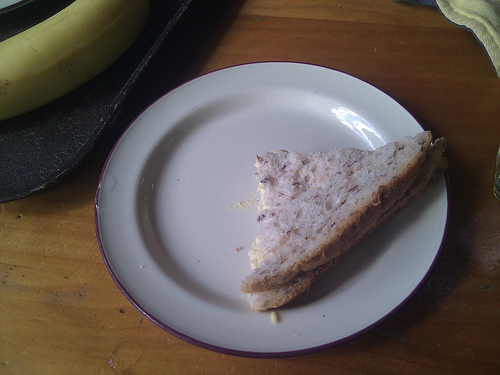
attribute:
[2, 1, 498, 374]
table — wooden, wood, brown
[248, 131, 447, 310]
sandwich — cut, brown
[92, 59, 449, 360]
plate — white, round, large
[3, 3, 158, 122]
banana — yellow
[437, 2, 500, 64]
fabric — yellow, green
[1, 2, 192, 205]
tray — black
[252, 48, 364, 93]
rim — purple, blue